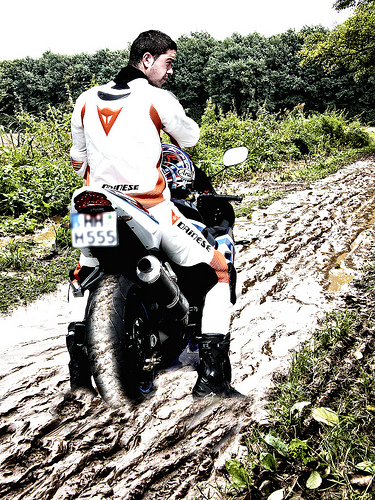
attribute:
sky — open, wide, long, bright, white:
[0, 6, 367, 63]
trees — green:
[6, 24, 373, 140]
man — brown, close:
[49, 26, 229, 252]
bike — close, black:
[69, 188, 252, 417]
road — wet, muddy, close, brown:
[2, 161, 373, 495]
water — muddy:
[318, 246, 360, 307]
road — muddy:
[240, 172, 346, 375]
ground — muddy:
[2, 176, 374, 495]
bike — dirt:
[60, 138, 257, 417]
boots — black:
[63, 322, 245, 401]